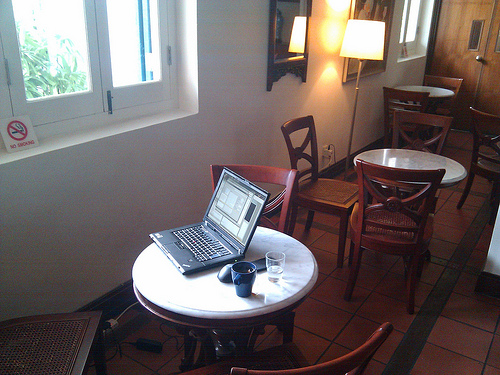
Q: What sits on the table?
A: A laptop.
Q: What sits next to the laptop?
A: A blue coffee mug.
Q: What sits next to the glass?
A: A cell phone.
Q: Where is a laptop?
A: On table.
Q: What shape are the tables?
A: Round.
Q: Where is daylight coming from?
A: Windows.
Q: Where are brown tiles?
A: On the floor.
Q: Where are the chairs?
A: Next to the tables.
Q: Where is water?
A: In a glass.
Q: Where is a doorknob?
A: On brown door.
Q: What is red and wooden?
A: Chairs.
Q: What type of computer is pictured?
A: Laptop.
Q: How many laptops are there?
A: One.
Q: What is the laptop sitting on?
A: A table.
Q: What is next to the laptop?
A: A mouse.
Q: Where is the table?
A: By the window.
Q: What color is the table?
A: White.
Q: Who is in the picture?
A: Nobody.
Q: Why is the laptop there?
A: Somebody is using it.